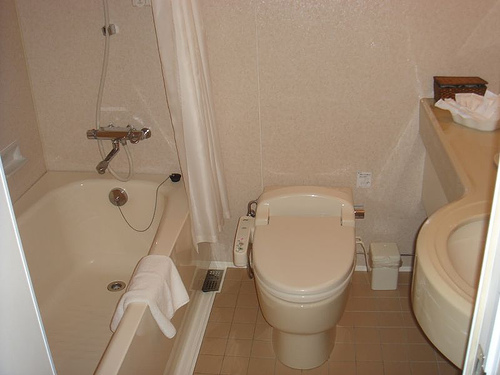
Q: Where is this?
A: This is at the bathroom.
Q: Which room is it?
A: It is a bathroom.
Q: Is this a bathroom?
A: Yes, it is a bathroom.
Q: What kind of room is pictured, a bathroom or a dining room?
A: It is a bathroom.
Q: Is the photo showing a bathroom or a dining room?
A: It is showing a bathroom.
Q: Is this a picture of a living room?
A: No, the picture is showing a bathroom.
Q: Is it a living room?
A: No, it is a bathroom.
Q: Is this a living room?
A: No, it is a bathroom.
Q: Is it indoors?
A: Yes, it is indoors.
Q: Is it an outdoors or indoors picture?
A: It is indoors.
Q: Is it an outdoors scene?
A: No, it is indoors.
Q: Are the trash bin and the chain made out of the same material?
A: No, the trash bin is made of plastic and the chain is made of metal.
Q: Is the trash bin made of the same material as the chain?
A: No, the trash bin is made of plastic and the chain is made of metal.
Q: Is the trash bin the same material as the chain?
A: No, the trash bin is made of plastic and the chain is made of metal.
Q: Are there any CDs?
A: No, there are no cds.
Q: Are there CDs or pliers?
A: No, there are no CDs or pliers.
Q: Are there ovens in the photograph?
A: No, there are no ovens.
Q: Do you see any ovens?
A: No, there are no ovens.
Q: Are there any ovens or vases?
A: No, there are no ovens or vases.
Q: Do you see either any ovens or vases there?
A: No, there are no ovens or vases.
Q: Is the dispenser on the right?
A: Yes, the dispenser is on the right of the image.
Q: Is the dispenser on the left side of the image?
A: No, the dispenser is on the right of the image.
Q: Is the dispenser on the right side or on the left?
A: The dispenser is on the right of the image.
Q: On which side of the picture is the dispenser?
A: The dispenser is on the right of the image.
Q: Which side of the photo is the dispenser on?
A: The dispenser is on the right of the image.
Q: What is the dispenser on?
A: The dispenser is on the counter.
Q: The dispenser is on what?
A: The dispenser is on the counter.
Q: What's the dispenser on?
A: The dispenser is on the counter.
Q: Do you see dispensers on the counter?
A: Yes, there is a dispenser on the counter.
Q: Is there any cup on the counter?
A: No, there is a dispenser on the counter.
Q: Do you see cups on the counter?
A: No, there is a dispenser on the counter.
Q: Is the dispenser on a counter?
A: Yes, the dispenser is on a counter.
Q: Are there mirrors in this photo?
A: No, there are no mirrors.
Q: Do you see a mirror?
A: No, there are no mirrors.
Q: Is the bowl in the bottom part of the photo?
A: Yes, the bowl is in the bottom of the image.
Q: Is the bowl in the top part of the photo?
A: No, the bowl is in the bottom of the image.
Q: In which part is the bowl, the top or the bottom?
A: The bowl is in the bottom of the image.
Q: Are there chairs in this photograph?
A: No, there are no chairs.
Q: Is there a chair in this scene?
A: No, there are no chairs.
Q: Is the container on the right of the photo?
A: Yes, the container is on the right of the image.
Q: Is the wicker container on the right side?
A: Yes, the container is on the right of the image.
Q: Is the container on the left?
A: No, the container is on the right of the image.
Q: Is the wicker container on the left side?
A: No, the container is on the right of the image.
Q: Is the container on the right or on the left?
A: The container is on the right of the image.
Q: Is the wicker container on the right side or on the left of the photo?
A: The container is on the right of the image.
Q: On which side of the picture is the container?
A: The container is on the right of the image.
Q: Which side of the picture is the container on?
A: The container is on the right of the image.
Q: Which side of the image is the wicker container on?
A: The container is on the right of the image.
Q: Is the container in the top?
A: Yes, the container is in the top of the image.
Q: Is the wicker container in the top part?
A: Yes, the container is in the top of the image.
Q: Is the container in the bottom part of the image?
A: No, the container is in the top of the image.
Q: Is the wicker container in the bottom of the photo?
A: No, the container is in the top of the image.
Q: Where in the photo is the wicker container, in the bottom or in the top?
A: The container is in the top of the image.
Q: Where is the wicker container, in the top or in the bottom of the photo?
A: The container is in the top of the image.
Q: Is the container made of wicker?
A: Yes, the container is made of wicker.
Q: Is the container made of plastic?
A: No, the container is made of wicker.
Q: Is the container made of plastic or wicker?
A: The container is made of wicker.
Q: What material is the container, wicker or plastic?
A: The container is made of wicker.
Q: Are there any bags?
A: No, there are no bags.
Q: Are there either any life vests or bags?
A: No, there are no bags or life vests.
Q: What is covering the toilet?
A: The lid is covering the toilet.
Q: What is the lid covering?
A: The lid is covering the toilet.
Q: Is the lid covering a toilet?
A: Yes, the lid is covering a toilet.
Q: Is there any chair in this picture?
A: No, there are no chairs.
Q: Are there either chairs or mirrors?
A: No, there are no chairs or mirrors.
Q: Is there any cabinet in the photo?
A: No, there are no cabinets.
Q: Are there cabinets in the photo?
A: No, there are no cabinets.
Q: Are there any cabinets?
A: No, there are no cabinets.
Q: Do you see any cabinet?
A: No, there are no cabinets.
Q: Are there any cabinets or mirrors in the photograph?
A: No, there are no cabinets or mirrors.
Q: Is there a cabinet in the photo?
A: No, there are no cabinets.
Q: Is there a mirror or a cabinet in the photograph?
A: No, there are no cabinets or mirrors.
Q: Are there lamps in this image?
A: No, there are no lamps.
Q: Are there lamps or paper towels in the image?
A: No, there are no lamps or paper towels.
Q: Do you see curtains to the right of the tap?
A: Yes, there is a curtain to the right of the tap.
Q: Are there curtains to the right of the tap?
A: Yes, there is a curtain to the right of the tap.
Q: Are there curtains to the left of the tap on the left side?
A: No, the curtain is to the right of the tap.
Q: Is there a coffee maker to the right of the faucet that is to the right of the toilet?
A: No, there is a curtain to the right of the tap.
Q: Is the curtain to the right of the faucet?
A: Yes, the curtain is to the right of the faucet.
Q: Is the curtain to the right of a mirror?
A: No, the curtain is to the right of the faucet.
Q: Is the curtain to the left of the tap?
A: No, the curtain is to the right of the tap.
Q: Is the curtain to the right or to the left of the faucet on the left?
A: The curtain is to the right of the tap.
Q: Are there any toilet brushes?
A: No, there are no toilet brushes.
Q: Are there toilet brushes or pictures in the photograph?
A: No, there are no toilet brushes or pictures.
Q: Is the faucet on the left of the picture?
A: Yes, the faucet is on the left of the image.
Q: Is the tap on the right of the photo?
A: No, the tap is on the left of the image.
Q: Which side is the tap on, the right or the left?
A: The tap is on the left of the image.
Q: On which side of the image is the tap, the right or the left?
A: The tap is on the left of the image.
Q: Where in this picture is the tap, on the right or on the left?
A: The tap is on the left of the image.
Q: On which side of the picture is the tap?
A: The tap is on the left of the image.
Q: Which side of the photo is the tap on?
A: The tap is on the left of the image.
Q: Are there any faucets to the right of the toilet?
A: Yes, there is a faucet to the right of the toilet.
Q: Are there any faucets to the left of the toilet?
A: No, the faucet is to the right of the toilet.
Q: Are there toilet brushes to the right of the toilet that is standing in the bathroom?
A: No, there is a faucet to the right of the toilet.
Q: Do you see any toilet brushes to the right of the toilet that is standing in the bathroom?
A: No, there is a faucet to the right of the toilet.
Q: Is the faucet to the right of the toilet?
A: Yes, the faucet is to the right of the toilet.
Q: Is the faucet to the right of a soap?
A: No, the faucet is to the right of the toilet.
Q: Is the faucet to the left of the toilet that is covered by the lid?
A: No, the faucet is to the right of the toilet.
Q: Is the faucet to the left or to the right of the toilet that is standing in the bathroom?
A: The faucet is to the right of the toilet.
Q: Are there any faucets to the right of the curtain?
A: No, the faucet is to the left of the curtain.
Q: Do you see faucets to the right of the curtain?
A: No, the faucet is to the left of the curtain.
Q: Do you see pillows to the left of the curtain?
A: No, there is a faucet to the left of the curtain.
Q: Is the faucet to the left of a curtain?
A: Yes, the faucet is to the left of a curtain.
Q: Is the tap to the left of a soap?
A: No, the tap is to the left of a curtain.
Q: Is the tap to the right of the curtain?
A: No, the tap is to the left of the curtain.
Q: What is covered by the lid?
A: The toilet is covered by the lid.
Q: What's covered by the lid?
A: The toilet is covered by the lid.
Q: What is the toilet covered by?
A: The toilet is covered by the lid.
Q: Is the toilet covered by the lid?
A: Yes, the toilet is covered by the lid.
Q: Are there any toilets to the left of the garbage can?
A: Yes, there is a toilet to the left of the garbage can.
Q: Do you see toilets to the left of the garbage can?
A: Yes, there is a toilet to the left of the garbage can.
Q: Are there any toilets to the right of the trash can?
A: No, the toilet is to the left of the trash can.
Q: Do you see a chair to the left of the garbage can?
A: No, there is a toilet to the left of the garbage can.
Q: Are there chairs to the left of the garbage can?
A: No, there is a toilet to the left of the garbage can.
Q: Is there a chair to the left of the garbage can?
A: No, there is a toilet to the left of the garbage can.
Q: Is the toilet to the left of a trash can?
A: Yes, the toilet is to the left of a trash can.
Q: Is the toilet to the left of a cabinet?
A: No, the toilet is to the left of a trash can.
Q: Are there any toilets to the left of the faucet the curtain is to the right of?
A: Yes, there is a toilet to the left of the tap.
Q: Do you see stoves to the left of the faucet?
A: No, there is a toilet to the left of the faucet.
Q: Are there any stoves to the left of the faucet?
A: No, there is a toilet to the left of the faucet.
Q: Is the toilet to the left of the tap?
A: Yes, the toilet is to the left of the tap.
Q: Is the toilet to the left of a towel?
A: No, the toilet is to the left of the tap.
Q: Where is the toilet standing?
A: The toilet is standing in the bathroom.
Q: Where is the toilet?
A: The toilet is in the bathroom.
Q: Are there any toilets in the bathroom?
A: Yes, there is a toilet in the bathroom.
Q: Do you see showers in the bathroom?
A: No, there is a toilet in the bathroom.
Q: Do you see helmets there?
A: No, there are no helmets.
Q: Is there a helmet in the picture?
A: No, there are no helmets.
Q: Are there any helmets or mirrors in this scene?
A: No, there are no helmets or mirrors.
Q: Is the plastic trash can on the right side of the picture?
A: Yes, the trash can is on the right of the image.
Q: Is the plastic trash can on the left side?
A: No, the garbage can is on the right of the image.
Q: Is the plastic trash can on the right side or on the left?
A: The garbage bin is on the right of the image.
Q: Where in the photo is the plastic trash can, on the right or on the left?
A: The garbage bin is on the right of the image.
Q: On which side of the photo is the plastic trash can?
A: The garbage can is on the right of the image.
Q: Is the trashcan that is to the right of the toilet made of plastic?
A: Yes, the garbage bin is made of plastic.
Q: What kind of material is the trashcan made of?
A: The trashcan is made of plastic.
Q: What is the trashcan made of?
A: The trashcan is made of plastic.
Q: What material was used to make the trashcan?
A: The trashcan is made of plastic.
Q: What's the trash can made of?
A: The trashcan is made of plastic.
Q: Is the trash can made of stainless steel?
A: No, the trash can is made of plastic.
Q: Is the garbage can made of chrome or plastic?
A: The garbage can is made of plastic.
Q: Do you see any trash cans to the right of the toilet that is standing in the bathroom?
A: Yes, there is a trash can to the right of the toilet.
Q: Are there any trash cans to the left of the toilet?
A: No, the trash can is to the right of the toilet.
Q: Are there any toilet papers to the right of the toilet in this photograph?
A: No, there is a trash can to the right of the toilet.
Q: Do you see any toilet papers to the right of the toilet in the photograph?
A: No, there is a trash can to the right of the toilet.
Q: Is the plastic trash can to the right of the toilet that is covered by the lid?
A: Yes, the garbage can is to the right of the toilet.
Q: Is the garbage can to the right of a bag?
A: No, the garbage can is to the right of the toilet.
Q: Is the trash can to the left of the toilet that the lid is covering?
A: No, the trash can is to the right of the toilet.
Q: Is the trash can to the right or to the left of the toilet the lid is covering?
A: The trash can is to the right of the toilet.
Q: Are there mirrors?
A: No, there are no mirrors.